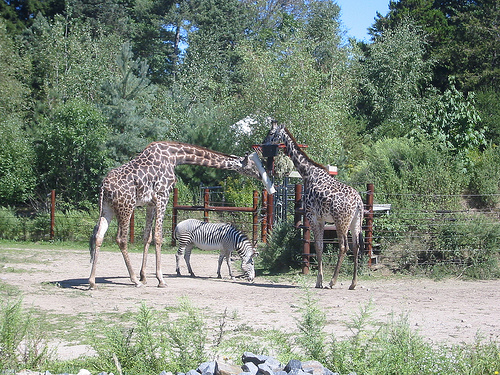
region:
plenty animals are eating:
[48, 101, 392, 293]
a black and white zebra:
[163, 195, 274, 302]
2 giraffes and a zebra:
[61, 76, 381, 271]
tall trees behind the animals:
[4, 8, 454, 203]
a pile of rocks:
[125, 345, 345, 372]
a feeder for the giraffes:
[259, 148, 296, 178]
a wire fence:
[370, 165, 488, 272]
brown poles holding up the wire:
[143, 180, 270, 232]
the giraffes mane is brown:
[268, 107, 331, 177]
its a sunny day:
[45, 40, 460, 335]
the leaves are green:
[282, 3, 469, 203]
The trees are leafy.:
[337, 68, 484, 199]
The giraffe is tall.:
[249, 120, 406, 282]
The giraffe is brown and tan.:
[262, 117, 365, 267]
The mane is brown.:
[260, 112, 354, 183]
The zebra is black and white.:
[159, 209, 276, 301]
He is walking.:
[82, 148, 219, 323]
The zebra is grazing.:
[171, 216, 281, 306]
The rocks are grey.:
[166, 340, 269, 372]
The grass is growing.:
[87, 311, 222, 373]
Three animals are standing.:
[57, 119, 397, 300]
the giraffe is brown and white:
[76, 87, 193, 267]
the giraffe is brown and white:
[113, 111, 230, 251]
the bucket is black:
[260, 141, 279, 160]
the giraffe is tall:
[262, 116, 392, 295]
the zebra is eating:
[169, 218, 269, 284]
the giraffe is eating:
[259, 113, 386, 295]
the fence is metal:
[394, 195, 469, 249]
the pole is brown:
[366, 184, 377, 258]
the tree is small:
[46, 97, 101, 202]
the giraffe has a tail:
[86, 174, 109, 261]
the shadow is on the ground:
[46, 264, 79, 293]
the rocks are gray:
[175, 349, 346, 373]